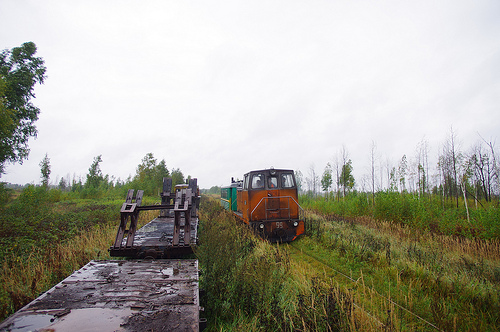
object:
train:
[220, 169, 307, 245]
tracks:
[276, 240, 441, 332]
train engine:
[252, 217, 305, 243]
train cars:
[220, 183, 237, 211]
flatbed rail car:
[0, 177, 201, 332]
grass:
[200, 192, 500, 332]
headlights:
[259, 222, 265, 229]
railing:
[250, 197, 305, 222]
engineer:
[260, 177, 275, 188]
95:
[276, 222, 284, 229]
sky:
[0, 0, 499, 198]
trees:
[320, 162, 333, 201]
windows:
[244, 175, 249, 189]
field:
[0, 177, 499, 332]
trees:
[38, 151, 51, 188]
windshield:
[250, 172, 296, 189]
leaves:
[2, 44, 26, 69]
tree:
[0, 41, 49, 176]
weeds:
[0, 202, 96, 253]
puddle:
[38, 306, 121, 332]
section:
[0, 0, 500, 332]